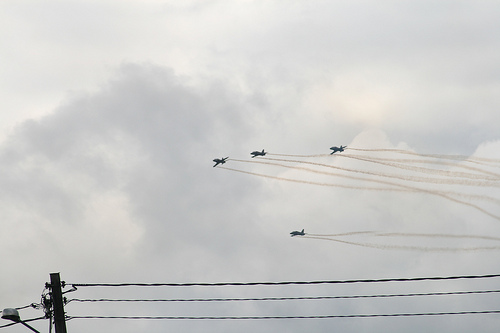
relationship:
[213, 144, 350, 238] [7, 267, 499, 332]
jets near electrical line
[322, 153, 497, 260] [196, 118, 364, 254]
smoke being released from planes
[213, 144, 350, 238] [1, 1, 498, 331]
jets flying in sky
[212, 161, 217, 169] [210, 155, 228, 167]
wing on flying airplane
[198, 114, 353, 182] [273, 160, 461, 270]
jets leaving behind smoke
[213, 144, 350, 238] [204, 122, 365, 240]
jets in formation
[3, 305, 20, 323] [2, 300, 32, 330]
bulb of a street lamp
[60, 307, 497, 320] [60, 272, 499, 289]
line running parallel to line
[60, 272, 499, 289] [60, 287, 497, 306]
line running parallel to line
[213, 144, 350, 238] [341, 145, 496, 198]
jets with smoke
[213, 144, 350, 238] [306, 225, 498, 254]
jets releasing smoke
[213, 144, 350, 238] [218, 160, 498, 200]
jets releasing smoke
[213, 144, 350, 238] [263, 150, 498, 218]
jets releasing smoke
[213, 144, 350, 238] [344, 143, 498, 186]
jets releasing smoke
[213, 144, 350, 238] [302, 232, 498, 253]
jets releasing smoke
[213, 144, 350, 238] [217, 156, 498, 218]
jets releasing smoke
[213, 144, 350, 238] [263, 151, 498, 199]
jets releasing smoke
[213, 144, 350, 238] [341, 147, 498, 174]
jets releasing smoke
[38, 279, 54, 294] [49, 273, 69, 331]
knob on pole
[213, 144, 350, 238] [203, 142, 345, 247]
jets in formation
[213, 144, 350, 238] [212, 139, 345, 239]
jets in formation